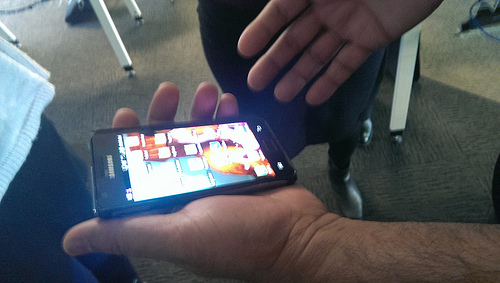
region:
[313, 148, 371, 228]
Person wearing black shoe.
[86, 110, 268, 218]
Person holding cell phone.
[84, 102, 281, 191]
Cellphone is turned on.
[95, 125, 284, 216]
Cellphone is in person's left hand.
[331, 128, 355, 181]
Person wearing black tights.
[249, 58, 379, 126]
Person wearing black skirt.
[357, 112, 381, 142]
Person wearing black shoe.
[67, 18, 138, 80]
White leg on object.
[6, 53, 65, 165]
Person wearing white sweater.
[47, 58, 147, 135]
Brown flooring in room.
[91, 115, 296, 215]
a black cellular phone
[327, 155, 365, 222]
a pair of black womans boots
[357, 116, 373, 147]
a mans black shoe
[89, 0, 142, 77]
a white metal leg of a table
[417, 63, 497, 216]
a carpeted office floor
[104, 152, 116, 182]
the logo name brand of the cell phone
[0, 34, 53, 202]
a white knit sweater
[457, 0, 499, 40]
a desk lamp on the floor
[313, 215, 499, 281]
the mans hairy left arm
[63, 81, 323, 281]
the mans left hand holding a cell phone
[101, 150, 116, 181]
Samsung brand name on cell phone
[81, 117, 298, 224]
Black cell phone in person's hand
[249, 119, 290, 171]
Buttons on black cell phone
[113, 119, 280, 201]
Lit up screen of cell phone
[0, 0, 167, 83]
White legs of table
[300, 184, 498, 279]
Left arm of person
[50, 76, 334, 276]
Left hand of person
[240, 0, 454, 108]
Right hand of person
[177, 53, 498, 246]
Gray carpet on floor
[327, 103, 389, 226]
Wheels on bottom of object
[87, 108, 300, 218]
samsung smartphone turned on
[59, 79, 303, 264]
person holding cell phone in their left hand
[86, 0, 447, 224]
righthand is gesturing towards cell phone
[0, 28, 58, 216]
a piece of clothing off to the side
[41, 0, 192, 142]
shadows on the ground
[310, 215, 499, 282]
hairy left arm in the corner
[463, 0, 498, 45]
a bluish cord in the corner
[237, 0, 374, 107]
four fingers of a hand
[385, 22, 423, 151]
table leg behind the hand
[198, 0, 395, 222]
black chair behind hand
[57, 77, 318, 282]
a cell phone on a hand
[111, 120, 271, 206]
screen of cell phone is color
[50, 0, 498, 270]
cell phone on a left hand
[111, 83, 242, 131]
right hand showing a cell phone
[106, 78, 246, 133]
four fingers on side of phone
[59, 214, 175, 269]
a thumb on side of cell phone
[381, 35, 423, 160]
leg of a table with a wheel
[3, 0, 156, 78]
white legs with wheels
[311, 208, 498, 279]
skin with black hair